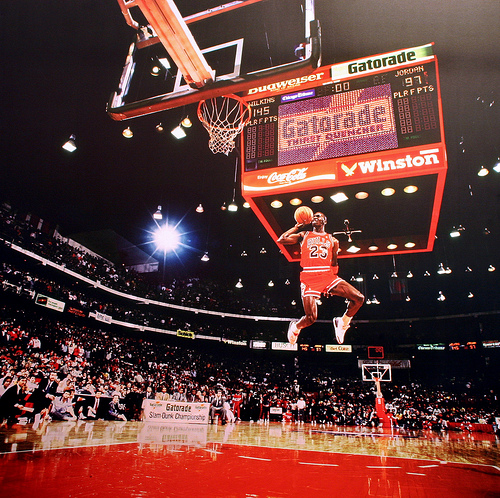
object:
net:
[197, 95, 252, 157]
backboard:
[105, 0, 324, 122]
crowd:
[1, 201, 499, 434]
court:
[2, 418, 498, 497]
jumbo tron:
[237, 41, 450, 264]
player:
[276, 205, 366, 347]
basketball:
[293, 206, 315, 227]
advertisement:
[277, 82, 399, 167]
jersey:
[299, 230, 334, 272]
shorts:
[300, 266, 346, 300]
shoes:
[329, 316, 350, 349]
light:
[127, 198, 207, 277]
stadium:
[1, 2, 494, 496]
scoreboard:
[243, 64, 437, 165]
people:
[84, 388, 109, 420]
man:
[1, 376, 29, 431]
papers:
[19, 405, 35, 414]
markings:
[363, 453, 408, 477]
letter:
[352, 152, 379, 178]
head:
[310, 210, 328, 228]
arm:
[272, 220, 309, 248]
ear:
[322, 213, 329, 226]